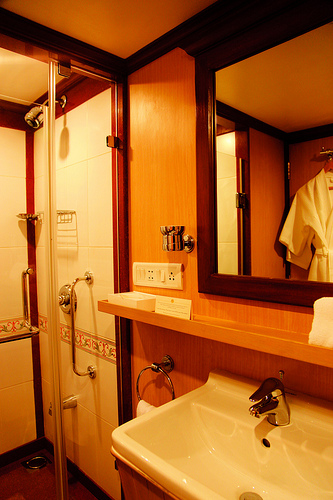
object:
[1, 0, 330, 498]
bathroom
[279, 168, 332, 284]
robe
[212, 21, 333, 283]
mirror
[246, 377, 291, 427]
faucet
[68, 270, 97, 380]
handle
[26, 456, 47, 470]
drain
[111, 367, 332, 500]
sink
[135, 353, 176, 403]
towel holder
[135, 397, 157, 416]
towel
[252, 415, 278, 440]
shadow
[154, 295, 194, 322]
sign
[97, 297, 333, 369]
shelf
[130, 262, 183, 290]
outlet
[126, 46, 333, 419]
wall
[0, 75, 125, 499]
shower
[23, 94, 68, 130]
shower head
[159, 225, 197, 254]
light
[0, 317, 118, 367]
tile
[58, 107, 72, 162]
shadow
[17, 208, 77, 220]
soap tray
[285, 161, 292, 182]
door hinge